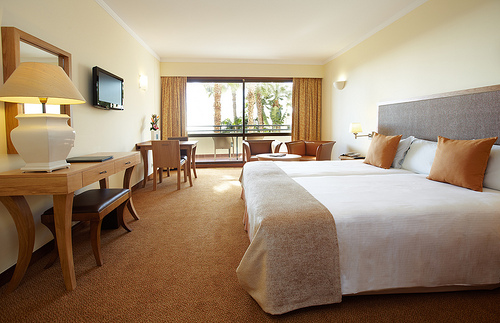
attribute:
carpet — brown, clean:
[151, 214, 235, 284]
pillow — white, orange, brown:
[429, 135, 469, 179]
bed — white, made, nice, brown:
[300, 165, 392, 240]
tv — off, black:
[92, 68, 131, 118]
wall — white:
[89, 19, 142, 60]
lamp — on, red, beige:
[12, 63, 84, 155]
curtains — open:
[165, 86, 186, 124]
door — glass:
[229, 75, 277, 121]